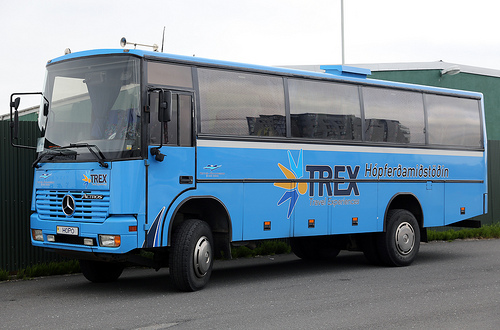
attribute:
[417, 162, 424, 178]
letter — black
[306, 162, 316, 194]
letter — black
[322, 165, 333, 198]
letter — black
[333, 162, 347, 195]
letter — black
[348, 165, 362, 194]
letter — black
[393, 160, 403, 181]
letter — black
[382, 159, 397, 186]
letter — black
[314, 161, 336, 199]
letter — black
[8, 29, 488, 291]
bus — blue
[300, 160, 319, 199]
letter — black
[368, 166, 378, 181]
letter — black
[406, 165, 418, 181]
letter — black